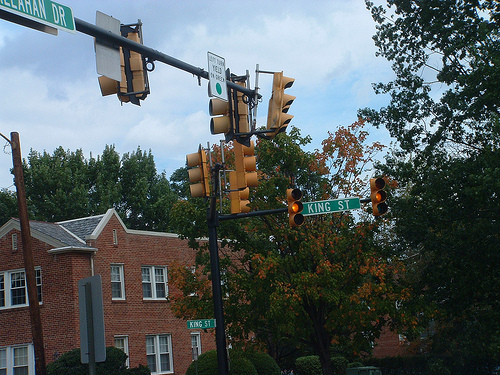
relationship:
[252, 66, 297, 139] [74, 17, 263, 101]
traffic light attached to pole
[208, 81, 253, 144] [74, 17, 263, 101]
traffic light attached to pole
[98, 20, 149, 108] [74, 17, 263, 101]
traffic light attached to pole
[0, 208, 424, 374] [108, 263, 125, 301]
building has window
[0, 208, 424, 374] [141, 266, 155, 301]
building has window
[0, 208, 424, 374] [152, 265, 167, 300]
building has window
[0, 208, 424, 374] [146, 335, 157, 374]
building has window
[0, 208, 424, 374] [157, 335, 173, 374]
building has window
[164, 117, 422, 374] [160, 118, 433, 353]
tree has leaves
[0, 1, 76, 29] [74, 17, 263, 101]
street sign attached to pole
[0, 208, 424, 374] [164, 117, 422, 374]
building behind tree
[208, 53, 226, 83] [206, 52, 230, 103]
writing on surface of sign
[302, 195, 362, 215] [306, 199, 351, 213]
sign says king st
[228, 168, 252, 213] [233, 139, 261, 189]
traffic light behind traffic light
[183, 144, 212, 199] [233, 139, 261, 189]
traffic light to left of traffic light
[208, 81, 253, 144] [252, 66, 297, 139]
traffic light next to traffic light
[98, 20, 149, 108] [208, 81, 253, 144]
traffic light to left of traffic light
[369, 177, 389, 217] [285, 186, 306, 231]
traffic light to right of traffic light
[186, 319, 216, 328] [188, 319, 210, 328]
king st says king st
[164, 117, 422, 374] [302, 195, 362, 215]
tree behind sign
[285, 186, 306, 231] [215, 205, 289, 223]
traffic light hanging from pole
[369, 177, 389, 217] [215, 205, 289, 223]
traffic light hanging from pole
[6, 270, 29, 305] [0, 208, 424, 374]
window part of building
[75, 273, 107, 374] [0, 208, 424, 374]
sign in front of building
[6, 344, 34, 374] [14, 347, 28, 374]
frame around window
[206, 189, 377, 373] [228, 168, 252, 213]
post supporting traffic light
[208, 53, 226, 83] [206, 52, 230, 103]
writing visible on sign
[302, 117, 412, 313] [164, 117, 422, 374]
leaves growing on tree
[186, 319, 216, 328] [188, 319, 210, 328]
king st for king st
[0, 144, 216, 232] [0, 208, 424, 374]
trees behind building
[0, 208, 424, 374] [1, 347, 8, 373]
building has window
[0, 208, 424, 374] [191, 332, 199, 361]
building has window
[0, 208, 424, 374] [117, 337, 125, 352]
building has window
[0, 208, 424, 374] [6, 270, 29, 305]
building has window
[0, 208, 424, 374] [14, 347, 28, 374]
building has window